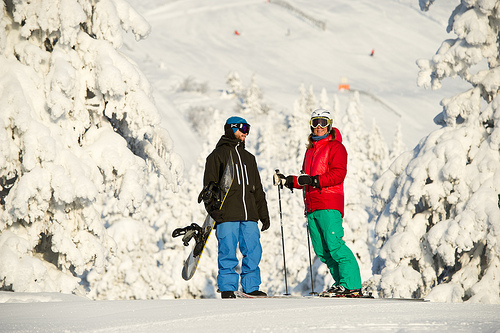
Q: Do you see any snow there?
A: Yes, there is snow.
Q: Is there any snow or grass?
A: Yes, there is snow.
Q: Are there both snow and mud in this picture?
A: No, there is snow but no mud.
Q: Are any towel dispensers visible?
A: No, there are no towel dispensers.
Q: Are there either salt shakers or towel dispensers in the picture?
A: No, there are no towel dispensers or salt shakers.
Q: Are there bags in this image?
A: No, there are no bags.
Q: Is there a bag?
A: No, there are no bags.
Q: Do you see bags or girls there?
A: No, there are no bags or girls.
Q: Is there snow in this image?
A: Yes, there is snow.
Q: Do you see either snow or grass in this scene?
A: Yes, there is snow.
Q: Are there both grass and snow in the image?
A: No, there is snow but no grass.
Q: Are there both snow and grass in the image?
A: No, there is snow but no grass.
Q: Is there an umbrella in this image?
A: No, there are no umbrellas.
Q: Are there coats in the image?
A: Yes, there is a coat.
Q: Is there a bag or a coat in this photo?
A: Yes, there is a coat.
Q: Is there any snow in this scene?
A: Yes, there is snow.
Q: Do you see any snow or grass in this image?
A: Yes, there is snow.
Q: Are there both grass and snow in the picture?
A: No, there is snow but no grass.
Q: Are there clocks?
A: No, there are no clocks.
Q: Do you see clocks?
A: No, there are no clocks.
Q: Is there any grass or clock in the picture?
A: No, there are no clocks or grass.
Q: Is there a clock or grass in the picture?
A: No, there are no clocks or grass.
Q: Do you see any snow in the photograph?
A: Yes, there is snow.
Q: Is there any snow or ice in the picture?
A: Yes, there is snow.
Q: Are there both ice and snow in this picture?
A: No, there is snow but no ice.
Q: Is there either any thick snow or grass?
A: Yes, there is thick snow.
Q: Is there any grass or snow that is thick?
A: Yes, the snow is thick.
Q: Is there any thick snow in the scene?
A: Yes, there is thick snow.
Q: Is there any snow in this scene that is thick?
A: Yes, there is snow that is thick.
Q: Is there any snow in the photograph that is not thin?
A: Yes, there is thick snow.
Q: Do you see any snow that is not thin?
A: Yes, there is thick snow.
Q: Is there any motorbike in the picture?
A: No, there are no motorcycles.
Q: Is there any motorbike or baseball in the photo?
A: No, there are no motorcycles or baseballs.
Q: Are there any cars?
A: No, there are no cars.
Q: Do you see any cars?
A: No, there are no cars.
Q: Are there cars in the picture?
A: No, there are no cars.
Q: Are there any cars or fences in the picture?
A: No, there are no cars or fences.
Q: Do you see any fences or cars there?
A: No, there are no cars or fences.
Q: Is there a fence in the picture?
A: No, there are no fences.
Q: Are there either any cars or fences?
A: No, there are no fences or cars.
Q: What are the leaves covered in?
A: The leaves are covered in snow.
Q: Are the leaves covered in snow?
A: Yes, the leaves are covered in snow.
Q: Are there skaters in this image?
A: No, there are no skaters.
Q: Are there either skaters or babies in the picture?
A: No, there are no skaters or babies.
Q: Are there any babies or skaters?
A: No, there are no skaters or babies.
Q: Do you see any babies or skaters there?
A: No, there are no skaters or babies.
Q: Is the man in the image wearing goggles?
A: Yes, the man is wearing goggles.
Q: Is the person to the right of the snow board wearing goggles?
A: Yes, the man is wearing goggles.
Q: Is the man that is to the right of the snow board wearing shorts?
A: No, the man is wearing goggles.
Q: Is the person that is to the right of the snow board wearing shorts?
A: No, the man is wearing goggles.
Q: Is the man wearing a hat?
A: Yes, the man is wearing a hat.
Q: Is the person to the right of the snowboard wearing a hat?
A: Yes, the man is wearing a hat.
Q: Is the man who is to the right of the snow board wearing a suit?
A: No, the man is wearing a hat.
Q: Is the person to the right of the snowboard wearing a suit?
A: No, the man is wearing a hat.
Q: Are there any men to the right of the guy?
A: Yes, there is a man to the right of the guy.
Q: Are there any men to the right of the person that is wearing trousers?
A: Yes, there is a man to the right of the guy.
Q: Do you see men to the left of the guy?
A: No, the man is to the right of the guy.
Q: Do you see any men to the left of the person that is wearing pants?
A: No, the man is to the right of the guy.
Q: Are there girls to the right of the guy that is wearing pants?
A: No, there is a man to the right of the guy.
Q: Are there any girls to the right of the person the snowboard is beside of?
A: No, there is a man to the right of the guy.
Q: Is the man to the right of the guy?
A: Yes, the man is to the right of the guy.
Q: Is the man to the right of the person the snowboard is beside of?
A: Yes, the man is to the right of the guy.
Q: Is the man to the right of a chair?
A: No, the man is to the right of the guy.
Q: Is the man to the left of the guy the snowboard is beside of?
A: No, the man is to the right of the guy.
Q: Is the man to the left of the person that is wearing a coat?
A: No, the man is to the right of the guy.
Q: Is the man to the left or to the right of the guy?
A: The man is to the right of the guy.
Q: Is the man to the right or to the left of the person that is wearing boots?
A: The man is to the right of the guy.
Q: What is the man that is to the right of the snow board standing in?
A: The man is standing in the snow.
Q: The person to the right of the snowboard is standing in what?
A: The man is standing in the snow.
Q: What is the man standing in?
A: The man is standing in the snow.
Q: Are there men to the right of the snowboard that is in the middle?
A: Yes, there is a man to the right of the snowboard.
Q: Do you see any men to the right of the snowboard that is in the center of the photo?
A: Yes, there is a man to the right of the snowboard.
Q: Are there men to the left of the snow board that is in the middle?
A: No, the man is to the right of the snowboard.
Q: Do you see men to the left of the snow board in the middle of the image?
A: No, the man is to the right of the snowboard.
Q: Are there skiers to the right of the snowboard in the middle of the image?
A: No, there is a man to the right of the snowboard.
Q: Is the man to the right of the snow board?
A: Yes, the man is to the right of the snow board.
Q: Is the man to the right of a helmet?
A: No, the man is to the right of the snow board.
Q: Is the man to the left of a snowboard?
A: No, the man is to the right of a snowboard.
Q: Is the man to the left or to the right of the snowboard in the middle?
A: The man is to the right of the snowboard.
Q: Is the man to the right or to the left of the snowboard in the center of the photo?
A: The man is to the right of the snowboard.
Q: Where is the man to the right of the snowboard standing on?
A: The man is standing on the snow.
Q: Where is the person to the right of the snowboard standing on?
A: The man is standing on the snow.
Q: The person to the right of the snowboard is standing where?
A: The man is standing on the snow.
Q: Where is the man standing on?
A: The man is standing on the snow.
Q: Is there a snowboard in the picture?
A: Yes, there is a snowboard.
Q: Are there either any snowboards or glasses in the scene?
A: Yes, there is a snowboard.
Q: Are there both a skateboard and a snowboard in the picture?
A: No, there is a snowboard but no skateboards.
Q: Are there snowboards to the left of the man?
A: Yes, there is a snowboard to the left of the man.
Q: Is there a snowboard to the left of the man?
A: Yes, there is a snowboard to the left of the man.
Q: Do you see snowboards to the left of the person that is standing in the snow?
A: Yes, there is a snowboard to the left of the man.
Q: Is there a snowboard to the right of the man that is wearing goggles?
A: No, the snowboard is to the left of the man.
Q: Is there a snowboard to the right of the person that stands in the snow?
A: No, the snowboard is to the left of the man.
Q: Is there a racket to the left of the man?
A: No, there is a snowboard to the left of the man.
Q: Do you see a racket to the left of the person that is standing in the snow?
A: No, there is a snowboard to the left of the man.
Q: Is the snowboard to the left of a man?
A: Yes, the snowboard is to the left of a man.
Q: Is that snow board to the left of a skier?
A: No, the snow board is to the left of a man.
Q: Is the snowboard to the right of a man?
A: No, the snowboard is to the left of a man.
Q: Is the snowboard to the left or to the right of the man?
A: The snowboard is to the left of the man.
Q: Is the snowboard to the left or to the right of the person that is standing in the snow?
A: The snowboard is to the left of the man.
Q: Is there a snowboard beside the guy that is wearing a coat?
A: Yes, there is a snowboard beside the guy.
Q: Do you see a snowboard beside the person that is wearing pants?
A: Yes, there is a snowboard beside the guy.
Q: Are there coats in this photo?
A: Yes, there is a coat.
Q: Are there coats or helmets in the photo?
A: Yes, there is a coat.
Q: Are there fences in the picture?
A: No, there are no fences.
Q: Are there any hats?
A: Yes, there is a hat.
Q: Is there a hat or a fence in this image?
A: Yes, there is a hat.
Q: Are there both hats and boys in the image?
A: No, there is a hat but no boys.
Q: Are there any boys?
A: No, there are no boys.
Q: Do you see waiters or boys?
A: No, there are no boys or waiters.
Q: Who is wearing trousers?
A: The guy is wearing trousers.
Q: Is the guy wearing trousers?
A: Yes, the guy is wearing trousers.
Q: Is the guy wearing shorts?
A: No, the guy is wearing trousers.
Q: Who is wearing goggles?
A: The guy is wearing goggles.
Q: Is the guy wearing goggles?
A: Yes, the guy is wearing goggles.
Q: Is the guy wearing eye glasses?
A: No, the guy is wearing goggles.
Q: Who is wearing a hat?
A: The guy is wearing a hat.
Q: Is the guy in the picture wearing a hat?
A: Yes, the guy is wearing a hat.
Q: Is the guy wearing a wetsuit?
A: No, the guy is wearing a hat.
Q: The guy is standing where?
A: The guy is standing on the snow.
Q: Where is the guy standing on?
A: The guy is standing on the snow.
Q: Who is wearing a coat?
A: The guy is wearing a coat.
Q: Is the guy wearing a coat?
A: Yes, the guy is wearing a coat.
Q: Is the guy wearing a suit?
A: No, the guy is wearing a coat.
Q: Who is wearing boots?
A: The guy is wearing boots.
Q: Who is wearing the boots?
A: The guy is wearing boots.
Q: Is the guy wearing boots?
A: Yes, the guy is wearing boots.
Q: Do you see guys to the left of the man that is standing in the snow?
A: Yes, there is a guy to the left of the man.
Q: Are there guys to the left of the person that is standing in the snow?
A: Yes, there is a guy to the left of the man.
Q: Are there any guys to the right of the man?
A: No, the guy is to the left of the man.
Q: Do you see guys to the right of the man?
A: No, the guy is to the left of the man.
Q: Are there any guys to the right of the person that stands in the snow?
A: No, the guy is to the left of the man.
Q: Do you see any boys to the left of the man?
A: No, there is a guy to the left of the man.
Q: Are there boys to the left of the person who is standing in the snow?
A: No, there is a guy to the left of the man.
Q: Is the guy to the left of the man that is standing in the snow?
A: Yes, the guy is to the left of the man.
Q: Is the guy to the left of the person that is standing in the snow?
A: Yes, the guy is to the left of the man.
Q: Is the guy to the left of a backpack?
A: No, the guy is to the left of the man.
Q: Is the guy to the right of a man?
A: No, the guy is to the left of a man.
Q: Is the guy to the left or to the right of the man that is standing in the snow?
A: The guy is to the left of the man.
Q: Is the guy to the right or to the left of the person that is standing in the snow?
A: The guy is to the left of the man.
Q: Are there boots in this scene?
A: Yes, there are boots.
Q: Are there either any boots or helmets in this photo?
A: Yes, there are boots.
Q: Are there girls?
A: No, there are no girls.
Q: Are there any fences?
A: No, there are no fences.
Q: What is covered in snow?
A: The ground is covered in snow.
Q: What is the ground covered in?
A: The ground is covered in snow.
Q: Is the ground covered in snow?
A: Yes, the ground is covered in snow.